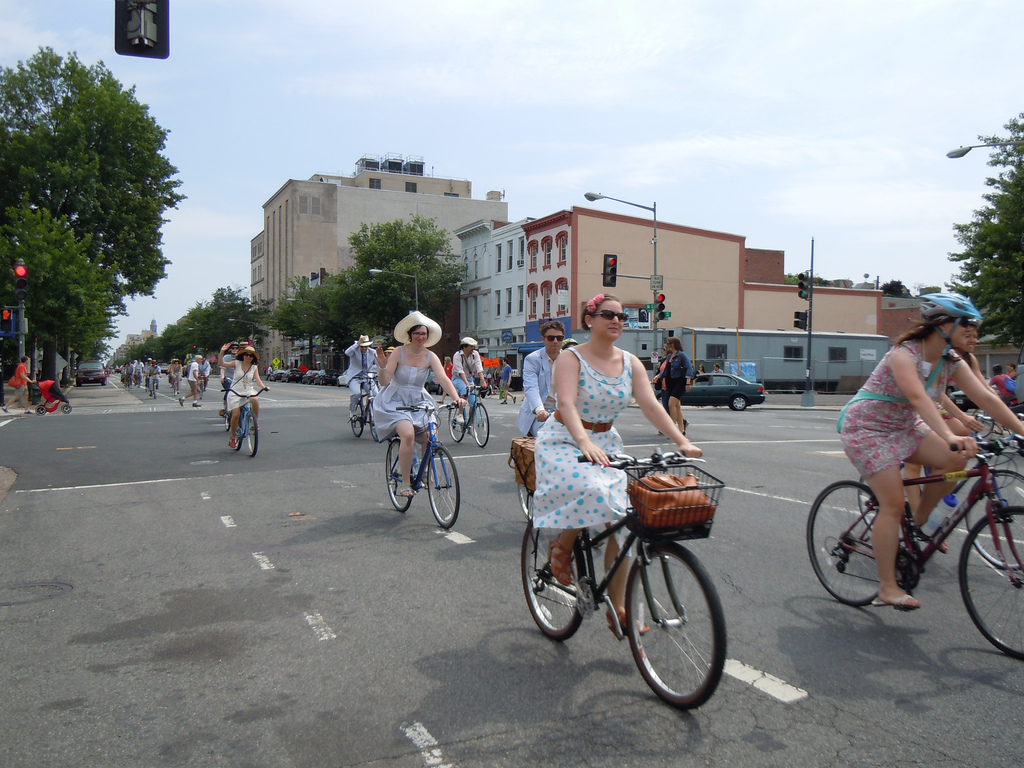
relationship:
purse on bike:
[629, 471, 717, 527] [447, 419, 800, 661]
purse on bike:
[606, 441, 751, 580] [486, 441, 811, 671]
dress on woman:
[823, 351, 990, 546] [760, 253, 1005, 599]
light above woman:
[71, 7, 182, 49] [8, 342, 52, 401]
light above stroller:
[71, 7, 182, 49] [30, 370, 97, 440]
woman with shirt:
[2, 356, 38, 414] [2, 357, 29, 381]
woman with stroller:
[2, 356, 38, 414] [30, 374, 63, 413]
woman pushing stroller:
[1, 352, 30, 411] [33, 380, 75, 419]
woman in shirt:
[1, 352, 30, 411] [7, 365, 34, 381]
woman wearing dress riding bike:
[532, 293, 704, 633] [354, 404, 469, 517]